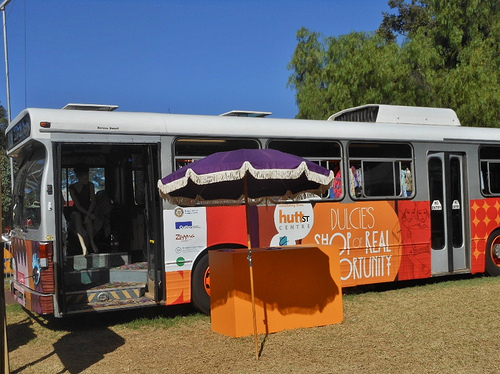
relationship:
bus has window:
[4, 100, 499, 320] [172, 137, 262, 154]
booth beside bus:
[205, 239, 360, 332] [0, 106, 498, 288]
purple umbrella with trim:
[157, 148, 334, 359] [155, 167, 333, 196]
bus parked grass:
[4, 100, 499, 320] [0, 270, 497, 371]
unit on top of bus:
[314, 81, 491, 145] [18, 104, 468, 314]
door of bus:
[424, 149, 449, 289] [12, 82, 493, 312]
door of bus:
[50, 138, 160, 315] [12, 82, 493, 312]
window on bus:
[345, 140, 417, 201] [4, 100, 499, 320]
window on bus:
[266, 138, 344, 203] [4, 100, 499, 320]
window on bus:
[476, 141, 500, 196] [4, 100, 499, 320]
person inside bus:
[53, 144, 137, 280] [4, 100, 499, 320]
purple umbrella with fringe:
[157, 148, 334, 359] [156, 161, 332, 206]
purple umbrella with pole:
[157, 148, 334, 359] [241, 171, 260, 358]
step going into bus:
[49, 269, 159, 306] [4, 100, 499, 320]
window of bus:
[345, 140, 417, 201] [4, 100, 499, 320]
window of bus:
[9, 155, 50, 232] [4, 100, 499, 320]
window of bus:
[345, 140, 417, 201] [8, 42, 498, 350]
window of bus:
[175, 140, 267, 162] [12, 82, 493, 312]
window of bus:
[266, 138, 344, 203] [12, 82, 493, 312]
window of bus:
[472, 141, 498, 187] [12, 82, 493, 312]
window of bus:
[476, 141, 500, 196] [4, 100, 499, 320]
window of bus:
[266, 138, 344, 203] [4, 100, 499, 320]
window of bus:
[169, 140, 267, 170] [4, 100, 499, 320]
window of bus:
[345, 143, 412, 201] [4, 100, 499, 320]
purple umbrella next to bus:
[157, 148, 334, 359] [2, 84, 499, 328]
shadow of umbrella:
[210, 250, 336, 307] [162, 151, 340, 209]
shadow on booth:
[210, 250, 336, 307] [208, 243, 345, 338]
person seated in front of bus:
[68, 162, 102, 257] [4, 100, 499, 320]